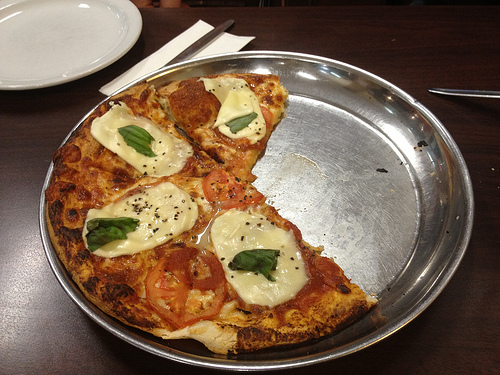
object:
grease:
[280, 152, 328, 186]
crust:
[233, 298, 372, 353]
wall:
[400, 102, 474, 323]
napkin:
[99, 19, 255, 96]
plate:
[0, 1, 143, 92]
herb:
[85, 217, 140, 253]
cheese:
[208, 212, 306, 309]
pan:
[44, 54, 477, 373]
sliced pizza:
[154, 71, 284, 179]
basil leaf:
[228, 249, 280, 282]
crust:
[157, 71, 282, 88]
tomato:
[144, 248, 227, 331]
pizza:
[42, 73, 378, 356]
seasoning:
[138, 198, 141, 200]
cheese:
[82, 182, 199, 258]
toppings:
[80, 141, 251, 252]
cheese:
[91, 99, 194, 179]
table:
[0, 0, 498, 375]